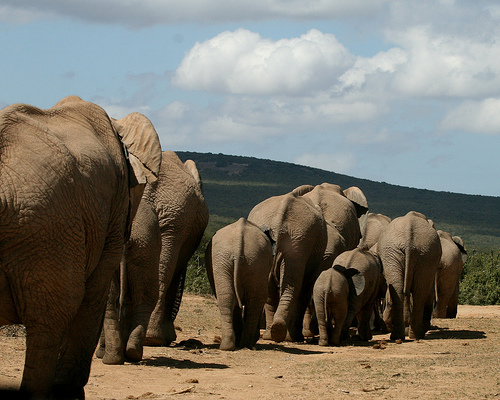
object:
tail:
[232, 258, 247, 319]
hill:
[161, 149, 500, 305]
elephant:
[205, 214, 272, 351]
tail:
[401, 231, 413, 294]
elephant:
[250, 191, 330, 342]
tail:
[271, 238, 285, 307]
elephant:
[310, 267, 355, 351]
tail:
[320, 282, 332, 322]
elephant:
[0, 95, 161, 400]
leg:
[22, 284, 107, 396]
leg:
[216, 275, 234, 352]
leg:
[410, 278, 435, 341]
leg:
[269, 264, 301, 343]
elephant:
[334, 241, 385, 343]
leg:
[354, 303, 372, 341]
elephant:
[433, 230, 468, 320]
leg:
[436, 279, 459, 318]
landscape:
[0, 91, 498, 399]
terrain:
[4, 281, 499, 400]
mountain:
[177, 147, 498, 209]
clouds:
[386, 23, 494, 103]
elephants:
[376, 210, 437, 343]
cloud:
[174, 27, 351, 100]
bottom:
[270, 318, 288, 343]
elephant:
[106, 136, 212, 367]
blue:
[1, 23, 140, 73]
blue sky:
[0, 3, 500, 197]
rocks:
[167, 376, 208, 397]